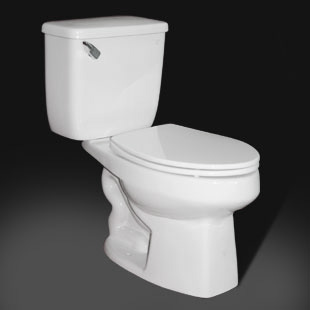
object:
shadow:
[232, 174, 300, 284]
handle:
[83, 40, 101, 59]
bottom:
[81, 123, 260, 188]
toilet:
[0, 0, 310, 310]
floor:
[14, 109, 308, 308]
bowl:
[84, 123, 260, 222]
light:
[187, 120, 225, 157]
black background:
[2, 2, 306, 169]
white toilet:
[41, 8, 261, 300]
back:
[39, 15, 172, 142]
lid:
[110, 123, 260, 171]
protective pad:
[110, 123, 260, 170]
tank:
[40, 16, 168, 141]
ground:
[65, 214, 298, 308]